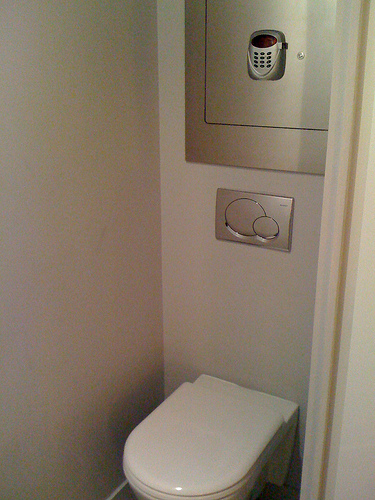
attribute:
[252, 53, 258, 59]
button — black, white, small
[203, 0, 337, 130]
safe — closed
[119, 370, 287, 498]
toilet lid — closed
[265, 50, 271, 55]
button — small, black, white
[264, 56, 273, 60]
button — small, black, white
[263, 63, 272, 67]
button — small, black, white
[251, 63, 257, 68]
button — small, black, white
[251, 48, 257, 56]
button — small, black, white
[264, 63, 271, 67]
button — white, small, black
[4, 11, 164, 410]
wall — clean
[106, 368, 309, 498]
lid — closed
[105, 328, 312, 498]
toilet — white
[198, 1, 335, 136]
door — silver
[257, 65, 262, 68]
button — small, black, white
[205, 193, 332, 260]
buttons — silver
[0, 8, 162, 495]
wall — cream colored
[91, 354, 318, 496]
top — closed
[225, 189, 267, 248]
plate — silver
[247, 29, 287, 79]
device — silver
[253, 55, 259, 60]
button — small, black, white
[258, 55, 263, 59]
button — white, black, small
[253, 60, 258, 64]
button — white, black, small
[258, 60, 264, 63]
button — white, black, small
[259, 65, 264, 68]
button — white, black, small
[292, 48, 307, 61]
circle — silver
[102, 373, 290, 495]
lid — down